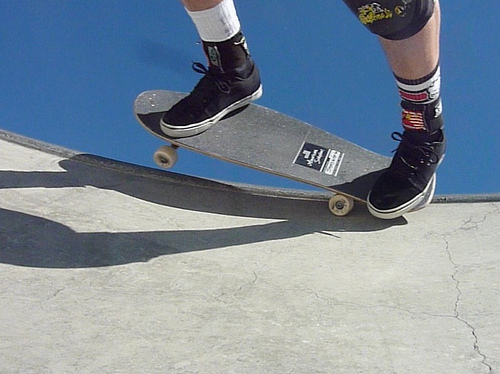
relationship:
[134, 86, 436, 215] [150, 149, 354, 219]
skateboard with wheels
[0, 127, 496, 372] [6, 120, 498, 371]
concrete skating ramp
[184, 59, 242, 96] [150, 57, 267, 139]
shoe laces on foot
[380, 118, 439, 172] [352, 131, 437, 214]
shoe laces on foot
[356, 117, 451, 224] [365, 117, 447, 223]
shoe on foot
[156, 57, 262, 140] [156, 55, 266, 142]
shoe on foot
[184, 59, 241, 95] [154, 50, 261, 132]
shoe laces on shoe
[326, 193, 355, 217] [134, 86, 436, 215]
wheel on skateboard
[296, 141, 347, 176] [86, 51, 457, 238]
design on skateboard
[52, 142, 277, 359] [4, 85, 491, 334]
shadow on ground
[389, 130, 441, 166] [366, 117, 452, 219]
shoe laces on shoe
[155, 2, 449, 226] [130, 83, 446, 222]
man on skateboard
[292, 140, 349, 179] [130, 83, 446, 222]
sticker on skateboard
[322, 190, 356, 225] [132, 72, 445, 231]
wheel on skateboard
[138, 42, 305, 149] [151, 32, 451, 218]
shoe on foot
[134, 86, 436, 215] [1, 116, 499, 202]
skateboard on ledge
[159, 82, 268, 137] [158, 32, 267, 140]
sole on shoe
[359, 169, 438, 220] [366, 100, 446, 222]
sole on shoe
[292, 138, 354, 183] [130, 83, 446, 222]
sticker on skateboard